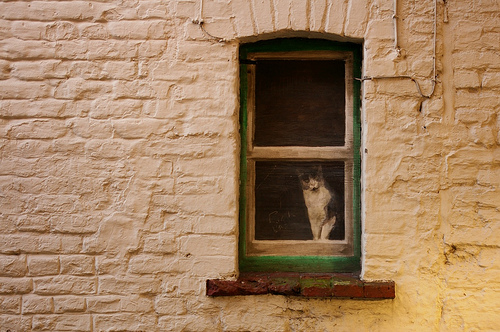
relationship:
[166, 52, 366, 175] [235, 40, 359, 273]
top pane of a double hung window